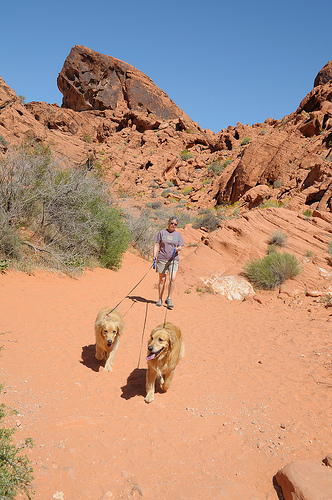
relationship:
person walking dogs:
[154, 217, 183, 309] [90, 303, 188, 404]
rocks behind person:
[2, 37, 331, 306] [154, 217, 183, 309]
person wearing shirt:
[154, 217, 183, 309] [155, 225, 186, 263]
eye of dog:
[110, 328, 116, 332] [142, 321, 187, 405]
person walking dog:
[154, 217, 183, 309] [143, 319, 184, 403]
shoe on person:
[157, 296, 173, 309] [154, 217, 183, 308]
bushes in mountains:
[0, 128, 312, 289] [1, 44, 330, 272]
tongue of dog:
[146, 351, 156, 360] [142, 321, 187, 405]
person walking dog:
[154, 217, 183, 308] [94, 307, 121, 372]